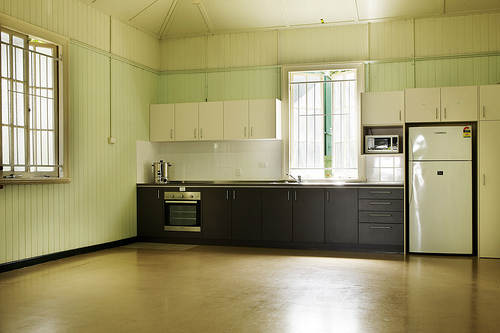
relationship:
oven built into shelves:
[145, 181, 205, 242] [144, 179, 402, 260]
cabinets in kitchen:
[149, 98, 281, 141] [5, 6, 484, 320]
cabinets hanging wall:
[149, 81, 483, 141] [71, 25, 268, 94]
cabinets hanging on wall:
[359, 82, 498, 123] [369, 27, 498, 92]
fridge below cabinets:
[406, 122, 475, 254] [357, 84, 497, 126]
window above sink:
[282, 63, 367, 180] [295, 176, 356, 188]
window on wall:
[282, 63, 367, 185] [212, 38, 409, 180]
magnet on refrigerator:
[459, 125, 474, 139] [401, 120, 476, 261]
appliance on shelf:
[361, 134, 401, 153] [358, 148, 406, 161]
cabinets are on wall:
[149, 98, 281, 141] [146, 37, 284, 112]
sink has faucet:
[265, 167, 336, 191] [276, 163, 311, 184]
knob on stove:
[167, 189, 175, 199] [159, 174, 204, 238]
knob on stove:
[176, 190, 186, 199] [159, 174, 204, 238]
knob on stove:
[187, 192, 196, 201] [159, 174, 204, 238]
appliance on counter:
[151, 159, 172, 184] [137, 174, 205, 190]